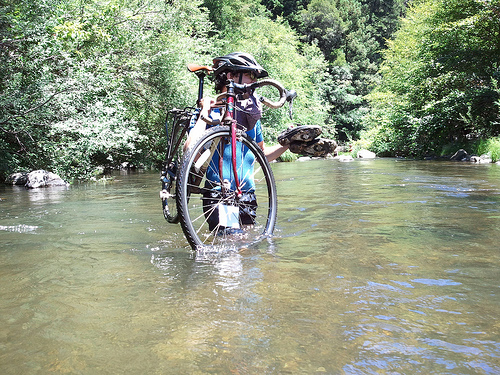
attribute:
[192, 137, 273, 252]
spokes — bike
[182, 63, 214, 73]
bike seat — orange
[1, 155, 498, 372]
water — calm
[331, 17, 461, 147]
green trees — thick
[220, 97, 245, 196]
bicycle — red metal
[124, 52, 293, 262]
bike — red-framed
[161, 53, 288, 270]
bike — reddish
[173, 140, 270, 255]
bike wheels — thick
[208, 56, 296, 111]
handle bars — curved, white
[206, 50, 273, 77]
helmet — black, bike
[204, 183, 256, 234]
pants — black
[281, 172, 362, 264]
water — thigh-high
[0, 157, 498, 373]
stream — large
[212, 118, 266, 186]
shirt — blue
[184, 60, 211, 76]
seat — reddish